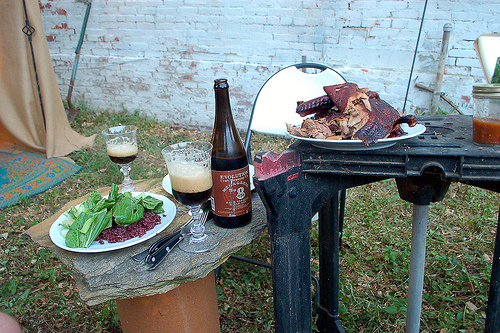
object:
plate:
[285, 121, 431, 152]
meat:
[354, 96, 403, 146]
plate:
[49, 186, 176, 253]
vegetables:
[63, 197, 109, 248]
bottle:
[203, 79, 253, 229]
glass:
[161, 138, 220, 255]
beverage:
[171, 186, 217, 206]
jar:
[471, 80, 500, 151]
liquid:
[472, 113, 500, 146]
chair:
[237, 58, 350, 211]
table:
[25, 168, 277, 310]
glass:
[102, 121, 140, 193]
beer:
[104, 148, 139, 165]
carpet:
[0, 143, 87, 207]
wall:
[40, 2, 498, 137]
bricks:
[148, 9, 198, 30]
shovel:
[59, 0, 100, 130]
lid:
[470, 82, 500, 100]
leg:
[264, 205, 323, 333]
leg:
[403, 205, 441, 331]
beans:
[99, 211, 161, 242]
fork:
[132, 201, 216, 272]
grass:
[342, 187, 418, 332]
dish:
[160, 164, 271, 197]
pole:
[430, 19, 456, 114]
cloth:
[2, 1, 88, 153]